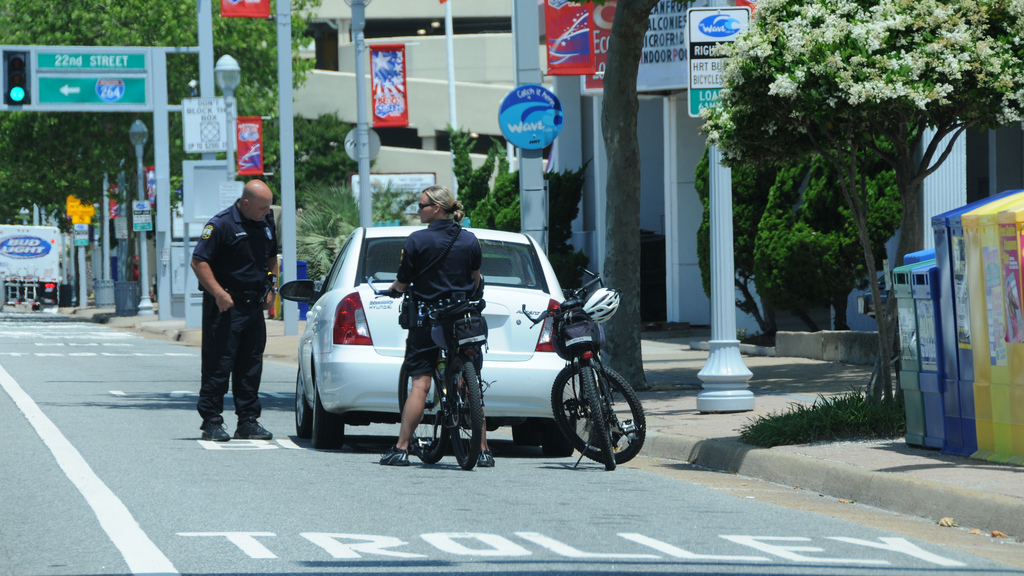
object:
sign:
[687, 6, 753, 90]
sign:
[635, 1, 692, 93]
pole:
[696, 144, 754, 413]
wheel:
[312, 380, 345, 448]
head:
[417, 185, 464, 222]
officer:
[380, 185, 497, 467]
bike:
[521, 265, 645, 470]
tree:
[695, 140, 903, 334]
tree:
[262, 109, 379, 252]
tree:
[0, 0, 315, 227]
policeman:
[191, 179, 279, 440]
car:
[279, 225, 600, 457]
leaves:
[728, 102, 875, 177]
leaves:
[725, 27, 912, 147]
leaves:
[693, 100, 914, 195]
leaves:
[753, 152, 903, 315]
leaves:
[693, 14, 858, 246]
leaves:
[744, 103, 902, 154]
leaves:
[775, 9, 873, 258]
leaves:
[786, 0, 991, 98]